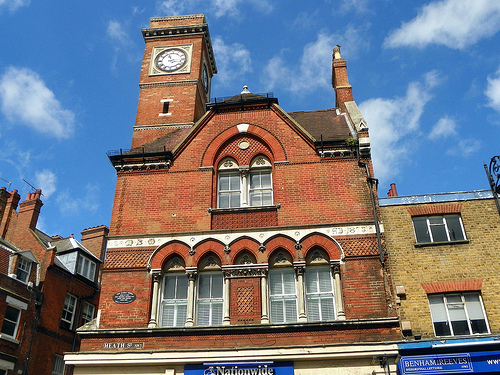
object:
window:
[247, 169, 274, 206]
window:
[262, 264, 299, 328]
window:
[155, 275, 185, 327]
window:
[302, 269, 339, 323]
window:
[73, 253, 85, 276]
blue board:
[408, 207, 470, 250]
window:
[58, 317, 73, 331]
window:
[213, 169, 243, 207]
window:
[193, 269, 225, 328]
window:
[302, 260, 339, 325]